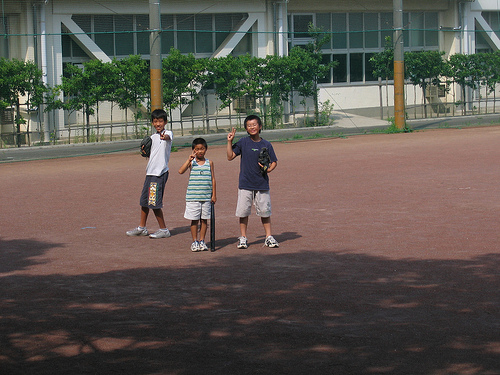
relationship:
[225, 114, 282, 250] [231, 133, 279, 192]
boy wearing shirt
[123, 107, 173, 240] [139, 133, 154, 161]
boy holding mitt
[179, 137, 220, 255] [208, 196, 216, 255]
boy holding bat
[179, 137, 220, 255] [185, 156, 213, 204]
boy wearing shirt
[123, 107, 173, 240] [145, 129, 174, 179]
boy wearing shirt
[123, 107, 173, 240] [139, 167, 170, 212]
boy wearing shorts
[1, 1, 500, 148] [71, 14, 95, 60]
building has window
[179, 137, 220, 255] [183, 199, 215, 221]
boy wearing shorts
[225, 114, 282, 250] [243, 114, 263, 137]
boy has hair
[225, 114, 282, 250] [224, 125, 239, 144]
boy holding two fingers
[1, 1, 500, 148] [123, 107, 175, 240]
building behind boy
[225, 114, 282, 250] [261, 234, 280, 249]
boy wearing shoe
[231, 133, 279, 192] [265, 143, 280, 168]
shirt has sleeve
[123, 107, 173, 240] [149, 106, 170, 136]
boy has head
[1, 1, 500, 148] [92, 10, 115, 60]
building has window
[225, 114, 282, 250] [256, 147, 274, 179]
boy holding glove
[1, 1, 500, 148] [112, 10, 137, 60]
building has window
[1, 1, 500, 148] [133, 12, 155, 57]
building has window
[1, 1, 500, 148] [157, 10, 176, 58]
building has window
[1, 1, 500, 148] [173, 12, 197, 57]
building has window